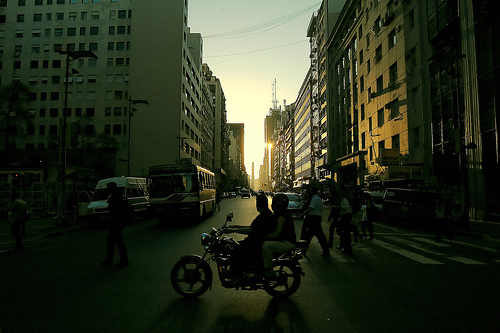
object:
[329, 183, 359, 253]
people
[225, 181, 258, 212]
street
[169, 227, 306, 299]
motorcycle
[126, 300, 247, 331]
road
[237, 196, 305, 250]
two people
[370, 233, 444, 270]
white lines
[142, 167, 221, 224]
bus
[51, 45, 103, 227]
streetlights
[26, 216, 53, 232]
sidewalk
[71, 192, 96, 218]
van door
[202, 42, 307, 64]
powerlines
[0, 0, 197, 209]
buildings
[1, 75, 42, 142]
tree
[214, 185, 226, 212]
person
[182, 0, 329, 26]
tops of buildings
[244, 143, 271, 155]
sun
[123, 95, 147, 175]
streetlamps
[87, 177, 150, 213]
white van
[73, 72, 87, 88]
windows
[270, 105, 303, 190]
apartment buildings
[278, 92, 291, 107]
flag pole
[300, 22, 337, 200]
buildings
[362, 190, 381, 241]
woman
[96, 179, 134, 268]
man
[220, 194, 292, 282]
man and woman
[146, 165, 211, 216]
front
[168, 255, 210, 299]
black tire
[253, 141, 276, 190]
light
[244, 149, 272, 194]
distance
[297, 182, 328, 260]
person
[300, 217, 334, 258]
black pants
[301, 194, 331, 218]
white shirt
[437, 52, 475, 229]
lamp post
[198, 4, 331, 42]
electrical wires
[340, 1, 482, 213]
buildings